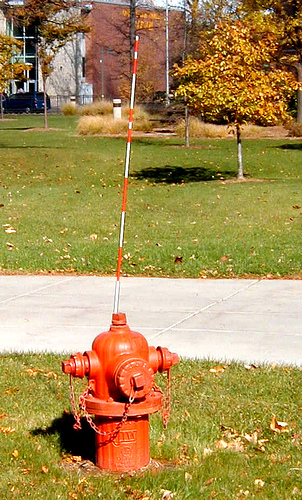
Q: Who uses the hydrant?
A: Fireman.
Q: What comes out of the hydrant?
A: Water.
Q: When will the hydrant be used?
A: In case of fire.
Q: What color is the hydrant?
A: Reddish orange.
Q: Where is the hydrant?
A: In the grass.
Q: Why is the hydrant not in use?
A: No fire.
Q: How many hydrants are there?
A: One.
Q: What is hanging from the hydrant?
A: Chains.